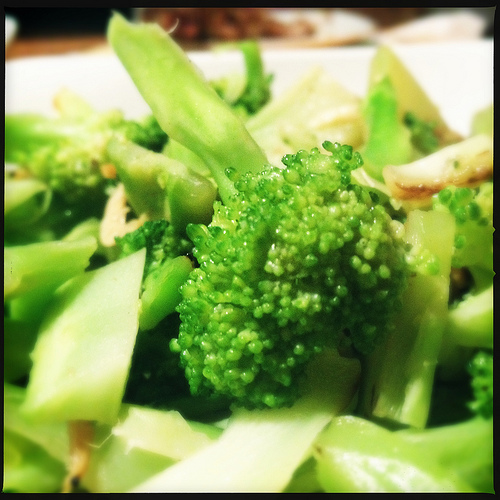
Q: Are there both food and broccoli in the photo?
A: Yes, there are both broccoli and food.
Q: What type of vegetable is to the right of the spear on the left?
A: The vegetable is broccoli.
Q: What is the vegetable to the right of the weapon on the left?
A: The vegetable is broccoli.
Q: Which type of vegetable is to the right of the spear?
A: The vegetable is broccoli.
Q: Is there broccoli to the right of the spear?
A: Yes, there is broccoli to the right of the spear.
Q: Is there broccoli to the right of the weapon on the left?
A: Yes, there is broccoli to the right of the spear.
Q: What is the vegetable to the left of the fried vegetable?
A: The vegetable is broccoli.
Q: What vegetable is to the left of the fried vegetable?
A: The vegetable is broccoli.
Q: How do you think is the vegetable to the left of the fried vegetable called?
A: The vegetable is broccoli.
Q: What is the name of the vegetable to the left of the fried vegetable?
A: The vegetable is broccoli.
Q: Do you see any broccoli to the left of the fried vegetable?
A: Yes, there is broccoli to the left of the vegetable.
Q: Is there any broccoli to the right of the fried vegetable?
A: No, the broccoli is to the left of the vegetable.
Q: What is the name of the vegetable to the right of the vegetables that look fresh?
A: The vegetable is broccoli.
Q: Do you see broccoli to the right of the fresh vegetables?
A: Yes, there is broccoli to the right of the veggies.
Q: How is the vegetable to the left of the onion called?
A: The vegetable is broccoli.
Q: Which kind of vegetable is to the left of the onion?
A: The vegetable is broccoli.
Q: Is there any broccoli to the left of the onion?
A: Yes, there is broccoli to the left of the onion.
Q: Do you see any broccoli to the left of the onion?
A: Yes, there is broccoli to the left of the onion.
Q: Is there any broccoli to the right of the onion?
A: No, the broccoli is to the left of the onion.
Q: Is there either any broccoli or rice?
A: Yes, there is broccoli.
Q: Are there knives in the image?
A: No, there are no knives.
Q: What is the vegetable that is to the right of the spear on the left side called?
A: The vegetable is broccoli.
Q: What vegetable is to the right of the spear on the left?
A: The vegetable is broccoli.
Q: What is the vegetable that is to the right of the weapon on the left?
A: The vegetable is broccoli.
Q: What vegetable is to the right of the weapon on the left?
A: The vegetable is broccoli.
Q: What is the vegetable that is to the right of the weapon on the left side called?
A: The vegetable is broccoli.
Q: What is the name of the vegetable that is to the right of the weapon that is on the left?
A: The vegetable is broccoli.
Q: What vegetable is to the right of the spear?
A: The vegetable is broccoli.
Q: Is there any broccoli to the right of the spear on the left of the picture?
A: Yes, there is broccoli to the right of the spear.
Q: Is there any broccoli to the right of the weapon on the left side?
A: Yes, there is broccoli to the right of the spear.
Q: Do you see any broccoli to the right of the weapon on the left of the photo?
A: Yes, there is broccoli to the right of the spear.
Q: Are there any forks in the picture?
A: No, there are no forks.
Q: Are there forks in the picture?
A: No, there are no forks.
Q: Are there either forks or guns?
A: No, there are no forks or guns.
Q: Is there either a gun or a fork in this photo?
A: No, there are no forks or guns.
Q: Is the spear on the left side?
A: Yes, the spear is on the left of the image.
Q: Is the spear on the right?
A: No, the spear is on the left of the image.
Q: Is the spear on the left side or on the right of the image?
A: The spear is on the left of the image.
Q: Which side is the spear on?
A: The spear is on the left of the image.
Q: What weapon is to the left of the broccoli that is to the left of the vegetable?
A: The weapon is a spear.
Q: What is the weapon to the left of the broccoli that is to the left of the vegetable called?
A: The weapon is a spear.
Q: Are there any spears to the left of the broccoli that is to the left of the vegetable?
A: Yes, there is a spear to the left of the broccoli.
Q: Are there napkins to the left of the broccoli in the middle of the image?
A: No, there is a spear to the left of the broccoli.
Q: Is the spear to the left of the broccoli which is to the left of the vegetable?
A: Yes, the spear is to the left of the broccoli.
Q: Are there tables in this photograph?
A: Yes, there is a table.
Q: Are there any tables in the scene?
A: Yes, there is a table.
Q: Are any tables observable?
A: Yes, there is a table.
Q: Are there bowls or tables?
A: Yes, there is a table.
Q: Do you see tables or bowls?
A: Yes, there is a table.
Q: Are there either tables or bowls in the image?
A: Yes, there is a table.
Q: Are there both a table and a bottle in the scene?
A: No, there is a table but no bottles.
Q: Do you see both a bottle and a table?
A: No, there is a table but no bottles.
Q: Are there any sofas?
A: No, there are no sofas.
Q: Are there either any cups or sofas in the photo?
A: No, there are no sofas or cups.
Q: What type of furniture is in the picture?
A: The furniture is a table.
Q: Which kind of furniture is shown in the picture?
A: The furniture is a table.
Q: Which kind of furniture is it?
A: The piece of furniture is a table.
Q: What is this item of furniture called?
A: This is a table.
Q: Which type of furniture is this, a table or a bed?
A: This is a table.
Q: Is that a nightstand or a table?
A: That is a table.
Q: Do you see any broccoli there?
A: Yes, there is broccoli.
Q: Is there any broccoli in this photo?
A: Yes, there is broccoli.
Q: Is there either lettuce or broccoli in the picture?
A: Yes, there is broccoli.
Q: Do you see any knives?
A: No, there are no knives.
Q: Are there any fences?
A: No, there are no fences.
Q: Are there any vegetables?
A: Yes, there are vegetables.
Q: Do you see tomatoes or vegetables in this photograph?
A: Yes, there are vegetables.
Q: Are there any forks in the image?
A: No, there are no forks.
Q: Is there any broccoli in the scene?
A: Yes, there is broccoli.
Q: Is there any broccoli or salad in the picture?
A: Yes, there is broccoli.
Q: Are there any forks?
A: No, there are no forks.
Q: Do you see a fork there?
A: No, there are no forks.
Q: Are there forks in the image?
A: No, there are no forks.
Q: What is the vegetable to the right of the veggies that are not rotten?
A: The vegetable is broccoli.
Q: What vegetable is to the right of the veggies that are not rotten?
A: The vegetable is broccoli.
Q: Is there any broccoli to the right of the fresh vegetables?
A: Yes, there is broccoli to the right of the vegetables.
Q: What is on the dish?
A: The broccoli is on the dish.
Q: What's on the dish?
A: The broccoli is on the dish.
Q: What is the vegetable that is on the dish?
A: The vegetable is broccoli.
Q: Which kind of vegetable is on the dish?
A: The vegetable is broccoli.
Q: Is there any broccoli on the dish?
A: Yes, there is broccoli on the dish.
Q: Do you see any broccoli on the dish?
A: Yes, there is broccoli on the dish.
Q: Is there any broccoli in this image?
A: Yes, there is broccoli.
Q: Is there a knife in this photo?
A: No, there are no knives.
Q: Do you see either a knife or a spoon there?
A: No, there are no knives or spoons.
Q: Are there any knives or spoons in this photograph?
A: No, there are no knives or spoons.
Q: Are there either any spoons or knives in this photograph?
A: No, there are no knives or spoons.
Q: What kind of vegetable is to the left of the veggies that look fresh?
A: The vegetable is broccoli.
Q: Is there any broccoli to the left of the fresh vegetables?
A: Yes, there is broccoli to the left of the vegetables.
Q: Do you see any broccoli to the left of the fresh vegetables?
A: Yes, there is broccoli to the left of the vegetables.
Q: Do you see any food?
A: Yes, there is food.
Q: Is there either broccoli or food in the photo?
A: Yes, there is food.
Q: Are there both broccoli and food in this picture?
A: Yes, there are both food and broccoli.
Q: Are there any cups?
A: No, there are no cups.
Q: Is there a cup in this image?
A: No, there are no cups.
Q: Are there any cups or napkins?
A: No, there are no cups or napkins.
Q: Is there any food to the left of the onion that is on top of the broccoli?
A: Yes, there is food to the left of the onion.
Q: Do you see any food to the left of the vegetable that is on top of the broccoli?
A: Yes, there is food to the left of the onion.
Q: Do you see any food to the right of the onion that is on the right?
A: No, the food is to the left of the onion.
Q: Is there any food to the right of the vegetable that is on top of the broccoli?
A: No, the food is to the left of the onion.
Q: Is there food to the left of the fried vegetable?
A: Yes, there is food to the left of the vegetable.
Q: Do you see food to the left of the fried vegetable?
A: Yes, there is food to the left of the vegetable.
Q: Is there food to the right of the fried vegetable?
A: No, the food is to the left of the vegetable.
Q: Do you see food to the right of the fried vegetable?
A: No, the food is to the left of the vegetable.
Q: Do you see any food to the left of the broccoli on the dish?
A: Yes, there is food to the left of the broccoli.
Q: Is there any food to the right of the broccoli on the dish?
A: No, the food is to the left of the broccoli.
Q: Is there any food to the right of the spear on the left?
A: Yes, there is food to the right of the spear.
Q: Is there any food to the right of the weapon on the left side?
A: Yes, there is food to the right of the spear.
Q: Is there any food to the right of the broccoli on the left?
A: Yes, there is food to the right of the broccoli.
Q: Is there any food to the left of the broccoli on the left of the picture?
A: No, the food is to the right of the broccoli.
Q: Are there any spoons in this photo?
A: No, there are no spoons.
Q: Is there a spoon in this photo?
A: No, there are no spoons.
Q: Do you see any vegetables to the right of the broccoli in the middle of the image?
A: Yes, there is a vegetable to the right of the broccoli.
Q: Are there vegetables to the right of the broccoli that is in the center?
A: Yes, there is a vegetable to the right of the broccoli.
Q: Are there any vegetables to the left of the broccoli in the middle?
A: No, the vegetable is to the right of the broccoli.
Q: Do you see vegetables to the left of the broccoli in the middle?
A: No, the vegetable is to the right of the broccoli.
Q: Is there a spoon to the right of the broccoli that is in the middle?
A: No, there is a vegetable to the right of the broccoli.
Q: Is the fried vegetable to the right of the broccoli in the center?
A: Yes, the vegetable is to the right of the broccoli.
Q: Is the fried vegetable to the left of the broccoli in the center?
A: No, the vegetable is to the right of the broccoli.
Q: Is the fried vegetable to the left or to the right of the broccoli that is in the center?
A: The vegetable is to the right of the broccoli.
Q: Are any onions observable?
A: Yes, there is an onion.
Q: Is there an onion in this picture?
A: Yes, there is an onion.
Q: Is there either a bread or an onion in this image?
A: Yes, there is an onion.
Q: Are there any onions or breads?
A: Yes, there is an onion.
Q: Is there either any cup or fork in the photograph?
A: No, there are no cups or forks.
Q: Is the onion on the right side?
A: Yes, the onion is on the right of the image.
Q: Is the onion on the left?
A: No, the onion is on the right of the image.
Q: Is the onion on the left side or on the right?
A: The onion is on the right of the image.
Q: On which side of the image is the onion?
A: The onion is on the right of the image.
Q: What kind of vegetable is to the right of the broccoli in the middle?
A: The vegetable is an onion.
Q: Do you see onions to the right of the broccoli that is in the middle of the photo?
A: Yes, there is an onion to the right of the broccoli.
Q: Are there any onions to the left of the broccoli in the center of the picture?
A: No, the onion is to the right of the broccoli.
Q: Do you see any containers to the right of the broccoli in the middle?
A: No, there is an onion to the right of the broccoli.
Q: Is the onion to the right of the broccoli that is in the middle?
A: Yes, the onion is to the right of the broccoli.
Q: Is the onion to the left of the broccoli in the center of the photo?
A: No, the onion is to the right of the broccoli.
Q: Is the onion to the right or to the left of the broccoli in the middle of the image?
A: The onion is to the right of the broccoli.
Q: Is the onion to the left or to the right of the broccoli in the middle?
A: The onion is to the right of the broccoli.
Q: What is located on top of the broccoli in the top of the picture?
A: The onion is on top of the broccoli.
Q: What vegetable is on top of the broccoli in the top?
A: The vegetable is an onion.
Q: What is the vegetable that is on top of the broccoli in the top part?
A: The vegetable is an onion.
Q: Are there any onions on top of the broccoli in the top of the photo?
A: Yes, there is an onion on top of the broccoli.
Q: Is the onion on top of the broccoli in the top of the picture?
A: Yes, the onion is on top of the broccoli.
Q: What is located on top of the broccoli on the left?
A: The onion is on top of the broccoli.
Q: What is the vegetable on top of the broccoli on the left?
A: The vegetable is an onion.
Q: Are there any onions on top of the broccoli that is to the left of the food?
A: Yes, there is an onion on top of the broccoli.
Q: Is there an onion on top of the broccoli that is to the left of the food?
A: Yes, there is an onion on top of the broccoli.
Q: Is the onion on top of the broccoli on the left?
A: Yes, the onion is on top of the broccoli.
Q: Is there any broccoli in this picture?
A: Yes, there is broccoli.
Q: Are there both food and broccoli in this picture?
A: Yes, there are both broccoli and food.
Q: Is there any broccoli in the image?
A: Yes, there is broccoli.